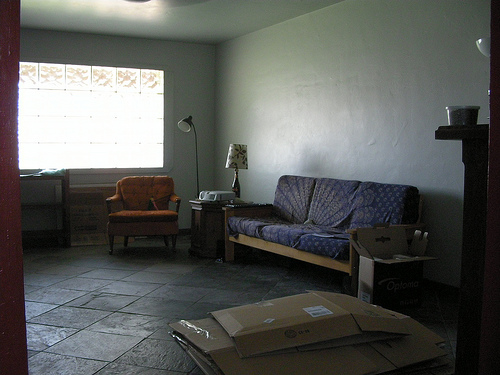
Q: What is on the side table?
A: Lamp.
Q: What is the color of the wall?
A: White.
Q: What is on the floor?
A: Boxes.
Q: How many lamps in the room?
A: Two.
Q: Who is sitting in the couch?
A: No one.